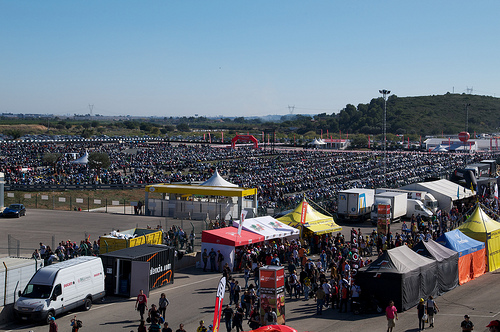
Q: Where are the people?
A: An event.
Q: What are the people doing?
A: Walking.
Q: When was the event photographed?
A: Daytime.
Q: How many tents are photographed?
A: Seven.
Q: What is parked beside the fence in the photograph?
A: A van.